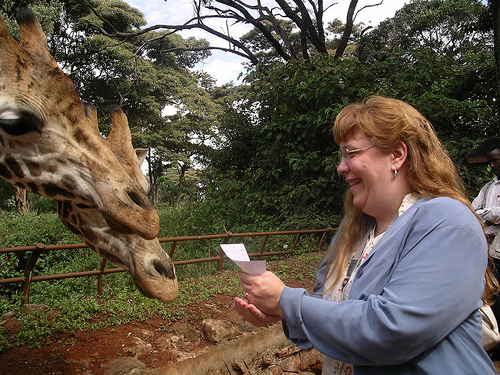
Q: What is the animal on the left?
A: A giraffe.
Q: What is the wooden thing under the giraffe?
A: A wooden fence.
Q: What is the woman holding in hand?
A: A piece of paper.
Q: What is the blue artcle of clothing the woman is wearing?
A: A shirt.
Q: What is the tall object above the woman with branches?
A: A tree.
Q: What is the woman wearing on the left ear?
A: An ear ring.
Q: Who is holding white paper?
A: The woman.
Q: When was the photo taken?
A: During daytime.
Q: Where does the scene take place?
A: At a zoo.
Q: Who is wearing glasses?
A: A woman.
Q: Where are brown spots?
A: On the giraffe.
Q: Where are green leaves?
A: On the trees.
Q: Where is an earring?
A: In woman's left ear.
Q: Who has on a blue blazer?
A: The lady.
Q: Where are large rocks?
A: On the ground.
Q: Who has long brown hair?
A: A lady.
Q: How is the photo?
A: Clear.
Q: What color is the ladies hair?
A: Brown.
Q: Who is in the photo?
A: A lady.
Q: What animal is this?
A: Giraffe.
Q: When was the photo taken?
A: Daytime.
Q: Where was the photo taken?
A: At a zoo.